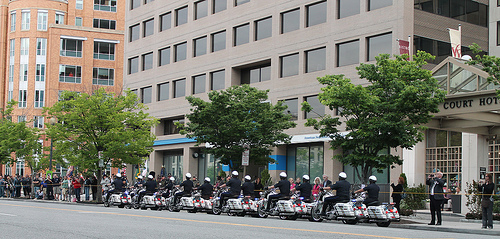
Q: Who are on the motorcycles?
A: Cops.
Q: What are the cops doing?
A: Riding motorcycles.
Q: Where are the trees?
A: On the sidewalk.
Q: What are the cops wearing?
A: Uniforms.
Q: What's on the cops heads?
A: Helmets.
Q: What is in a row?
A: The cops.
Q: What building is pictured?
A: Courthouse.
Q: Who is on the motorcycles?
A: Police officers.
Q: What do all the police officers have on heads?
A: Helmets.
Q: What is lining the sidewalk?
A: Trees.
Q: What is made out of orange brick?
A: Building to the left.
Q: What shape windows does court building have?
A: Square.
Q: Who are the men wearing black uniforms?
A: Police officers.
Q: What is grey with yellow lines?
A: Road.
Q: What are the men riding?
A: Motorcycles.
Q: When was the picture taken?
A: During the day.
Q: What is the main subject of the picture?
A: A police formation.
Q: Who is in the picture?
A: Police officers and spectators.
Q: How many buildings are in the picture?
A: Two.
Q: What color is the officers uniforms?
A: Black.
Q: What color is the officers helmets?
A: White.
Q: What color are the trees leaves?
A: Green.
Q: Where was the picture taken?
A: In the city street.